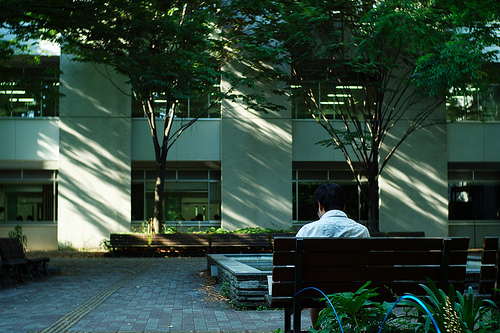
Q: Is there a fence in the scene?
A: No, there are no fences.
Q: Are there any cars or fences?
A: No, there are no fences or cars.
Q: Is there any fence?
A: No, there are no fences.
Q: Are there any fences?
A: No, there are no fences.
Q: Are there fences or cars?
A: No, there are no fences or cars.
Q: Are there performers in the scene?
A: No, there are no performers.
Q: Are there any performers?
A: No, there are no performers.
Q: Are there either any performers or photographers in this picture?
A: No, there are no performers or photographers.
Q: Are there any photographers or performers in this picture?
A: No, there are no performers or photographers.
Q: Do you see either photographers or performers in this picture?
A: No, there are no performers or photographers.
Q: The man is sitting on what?
A: The man is sitting on the bench.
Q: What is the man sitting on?
A: The man is sitting on the bench.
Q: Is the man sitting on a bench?
A: Yes, the man is sitting on a bench.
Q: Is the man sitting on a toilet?
A: No, the man is sitting on a bench.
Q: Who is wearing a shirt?
A: The man is wearing a shirt.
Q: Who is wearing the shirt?
A: The man is wearing a shirt.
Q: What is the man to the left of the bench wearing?
A: The man is wearing a shirt.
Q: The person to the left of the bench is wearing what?
A: The man is wearing a shirt.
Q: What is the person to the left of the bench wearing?
A: The man is wearing a shirt.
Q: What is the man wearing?
A: The man is wearing a shirt.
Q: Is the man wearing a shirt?
A: Yes, the man is wearing a shirt.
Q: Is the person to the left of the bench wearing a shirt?
A: Yes, the man is wearing a shirt.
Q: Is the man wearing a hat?
A: No, the man is wearing a shirt.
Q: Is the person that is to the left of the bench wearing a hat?
A: No, the man is wearing a shirt.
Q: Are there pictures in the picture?
A: No, there are no pictures.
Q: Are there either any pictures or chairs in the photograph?
A: No, there are no pictures or chairs.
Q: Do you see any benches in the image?
A: Yes, there is a bench.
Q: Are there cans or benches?
A: Yes, there is a bench.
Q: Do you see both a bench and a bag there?
A: No, there is a bench but no bags.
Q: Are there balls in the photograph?
A: No, there are no balls.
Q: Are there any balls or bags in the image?
A: No, there are no balls or bags.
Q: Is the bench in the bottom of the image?
A: Yes, the bench is in the bottom of the image.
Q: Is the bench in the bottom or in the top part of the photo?
A: The bench is in the bottom of the image.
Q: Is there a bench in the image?
A: Yes, there is a bench.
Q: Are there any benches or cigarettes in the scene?
A: Yes, there is a bench.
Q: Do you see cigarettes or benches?
A: Yes, there is a bench.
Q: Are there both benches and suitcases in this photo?
A: No, there is a bench but no suitcases.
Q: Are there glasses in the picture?
A: No, there are no glasses.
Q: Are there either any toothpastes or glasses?
A: No, there are no glasses or toothpastes.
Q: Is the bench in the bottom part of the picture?
A: Yes, the bench is in the bottom of the image.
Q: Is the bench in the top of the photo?
A: No, the bench is in the bottom of the image.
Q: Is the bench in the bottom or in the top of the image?
A: The bench is in the bottom of the image.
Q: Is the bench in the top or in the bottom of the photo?
A: The bench is in the bottom of the image.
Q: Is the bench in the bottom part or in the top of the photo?
A: The bench is in the bottom of the image.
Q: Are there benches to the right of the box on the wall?
A: Yes, there is a bench to the right of the box.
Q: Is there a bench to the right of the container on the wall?
A: Yes, there is a bench to the right of the box.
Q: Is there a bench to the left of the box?
A: No, the bench is to the right of the box.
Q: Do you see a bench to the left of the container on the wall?
A: No, the bench is to the right of the box.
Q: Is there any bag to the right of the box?
A: No, there is a bench to the right of the box.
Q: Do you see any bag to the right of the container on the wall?
A: No, there is a bench to the right of the box.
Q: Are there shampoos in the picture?
A: No, there are no shampoos.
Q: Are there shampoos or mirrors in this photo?
A: No, there are no shampoos or mirrors.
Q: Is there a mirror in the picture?
A: No, there are no mirrors.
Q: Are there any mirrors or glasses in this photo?
A: No, there are no mirrors or glasses.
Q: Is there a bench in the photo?
A: Yes, there is a bench.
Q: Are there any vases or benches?
A: Yes, there is a bench.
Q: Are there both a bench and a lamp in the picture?
A: No, there is a bench but no lamps.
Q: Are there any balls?
A: No, there are no balls.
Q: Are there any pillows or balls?
A: No, there are no balls or pillows.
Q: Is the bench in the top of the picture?
A: No, the bench is in the bottom of the image.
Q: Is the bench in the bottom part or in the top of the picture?
A: The bench is in the bottom of the image.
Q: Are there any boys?
A: No, there are no boys.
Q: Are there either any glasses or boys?
A: No, there are no boys or glasses.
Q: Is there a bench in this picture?
A: Yes, there is a bench.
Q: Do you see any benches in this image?
A: Yes, there is a bench.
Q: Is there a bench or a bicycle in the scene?
A: Yes, there is a bench.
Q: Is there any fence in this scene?
A: No, there are no fences.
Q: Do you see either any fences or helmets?
A: No, there are no fences or helmets.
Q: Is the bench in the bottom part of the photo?
A: Yes, the bench is in the bottom of the image.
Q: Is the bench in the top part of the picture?
A: No, the bench is in the bottom of the image.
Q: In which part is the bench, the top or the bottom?
A: The bench is in the bottom of the image.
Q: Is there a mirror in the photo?
A: No, there are no mirrors.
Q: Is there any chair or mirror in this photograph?
A: No, there are no mirrors or chairs.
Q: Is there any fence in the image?
A: No, there are no fences.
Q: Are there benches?
A: Yes, there is a bench.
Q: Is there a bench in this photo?
A: Yes, there is a bench.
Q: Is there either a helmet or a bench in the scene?
A: Yes, there is a bench.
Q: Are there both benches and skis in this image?
A: No, there is a bench but no skis.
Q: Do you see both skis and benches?
A: No, there is a bench but no skis.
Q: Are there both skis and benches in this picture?
A: No, there is a bench but no skis.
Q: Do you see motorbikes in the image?
A: No, there are no motorbikes.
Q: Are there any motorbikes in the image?
A: No, there are no motorbikes.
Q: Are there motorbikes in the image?
A: No, there are no motorbikes.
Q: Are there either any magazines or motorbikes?
A: No, there are no motorbikes or magazines.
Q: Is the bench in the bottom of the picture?
A: Yes, the bench is in the bottom of the image.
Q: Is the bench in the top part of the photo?
A: No, the bench is in the bottom of the image.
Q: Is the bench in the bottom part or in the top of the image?
A: The bench is in the bottom of the image.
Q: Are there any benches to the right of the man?
A: Yes, there is a bench to the right of the man.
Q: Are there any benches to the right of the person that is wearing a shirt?
A: Yes, there is a bench to the right of the man.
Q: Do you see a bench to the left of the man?
A: No, the bench is to the right of the man.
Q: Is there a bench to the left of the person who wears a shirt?
A: No, the bench is to the right of the man.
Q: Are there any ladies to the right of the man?
A: No, there is a bench to the right of the man.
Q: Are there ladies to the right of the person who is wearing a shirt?
A: No, there is a bench to the right of the man.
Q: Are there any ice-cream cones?
A: No, there are no ice-cream cones.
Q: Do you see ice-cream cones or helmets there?
A: No, there are no ice-cream cones or helmets.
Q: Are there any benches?
A: Yes, there is a bench.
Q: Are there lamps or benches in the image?
A: Yes, there is a bench.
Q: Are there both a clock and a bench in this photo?
A: No, there is a bench but no clocks.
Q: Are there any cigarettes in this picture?
A: No, there are no cigarettes.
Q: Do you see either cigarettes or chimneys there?
A: No, there are no cigarettes or chimneys.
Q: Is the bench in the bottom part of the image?
A: Yes, the bench is in the bottom of the image.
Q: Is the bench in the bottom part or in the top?
A: The bench is in the bottom of the image.